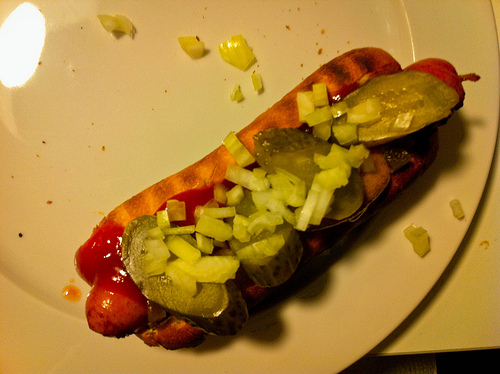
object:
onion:
[173, 252, 241, 283]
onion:
[294, 190, 319, 232]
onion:
[308, 188, 335, 225]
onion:
[164, 266, 197, 298]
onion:
[195, 233, 214, 254]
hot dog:
[85, 58, 480, 339]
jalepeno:
[250, 128, 365, 220]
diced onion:
[221, 131, 257, 168]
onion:
[223, 163, 271, 190]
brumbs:
[6, 130, 113, 216]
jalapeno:
[122, 214, 249, 338]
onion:
[225, 185, 244, 206]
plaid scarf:
[311, 84, 332, 107]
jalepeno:
[333, 70, 459, 148]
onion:
[194, 217, 232, 242]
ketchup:
[72, 179, 236, 307]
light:
[0, 0, 45, 89]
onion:
[165, 233, 201, 263]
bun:
[74, 47, 481, 352]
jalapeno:
[226, 189, 303, 287]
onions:
[96, 14, 136, 39]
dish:
[0, 0, 499, 374]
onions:
[347, 99, 382, 125]